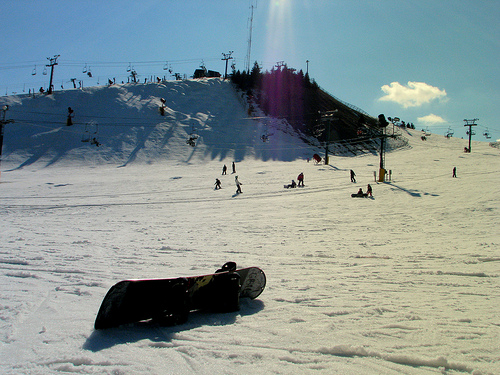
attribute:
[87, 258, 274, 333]
snowboard — black, dark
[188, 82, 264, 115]
hill — snow covered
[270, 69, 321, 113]
hill — grass covered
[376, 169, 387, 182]
post — yellow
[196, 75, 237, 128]
hill side — snowy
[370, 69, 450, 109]
cloud — white, fluffy, puffy, small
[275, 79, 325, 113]
forest — green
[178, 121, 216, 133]
snow — white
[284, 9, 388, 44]
sky — blue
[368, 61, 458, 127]
clouds — white